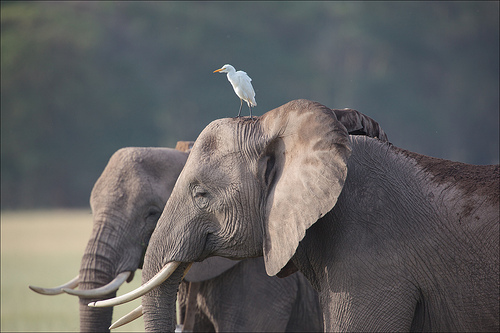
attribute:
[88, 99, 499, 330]
elephant — wrinkly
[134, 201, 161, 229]
expression — placid, content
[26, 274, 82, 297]
tusk — upturned, white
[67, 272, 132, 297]
tusk — upturned, white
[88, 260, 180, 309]
tusk — white, upturned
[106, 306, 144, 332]
tusk — upturned, white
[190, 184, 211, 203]
eye — large